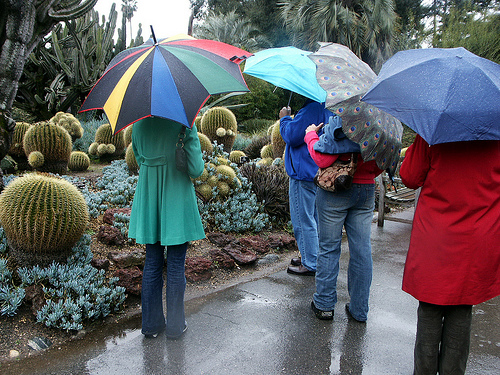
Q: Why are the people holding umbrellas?
A: Because it is raining.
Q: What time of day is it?
A: Daytime.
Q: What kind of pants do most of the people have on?
A: Jeans.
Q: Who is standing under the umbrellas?
A: Men and women.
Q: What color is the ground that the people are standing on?
A: Black.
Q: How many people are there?
A: Four.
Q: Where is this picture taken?
A: Outside in a public area.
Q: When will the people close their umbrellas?
A: When they get out of the rain.